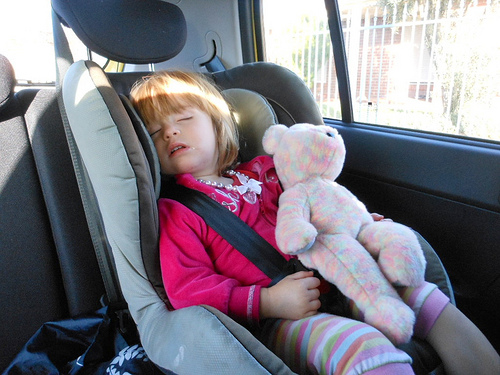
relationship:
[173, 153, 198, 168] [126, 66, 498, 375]
chin of child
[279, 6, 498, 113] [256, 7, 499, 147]
fence through window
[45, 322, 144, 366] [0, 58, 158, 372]
blue article in seat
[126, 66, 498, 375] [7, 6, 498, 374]
child in car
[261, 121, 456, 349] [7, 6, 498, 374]
bear in car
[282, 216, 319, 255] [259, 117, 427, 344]
paw of bear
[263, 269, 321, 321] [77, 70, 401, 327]
hand of kid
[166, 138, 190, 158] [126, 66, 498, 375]
mouth of child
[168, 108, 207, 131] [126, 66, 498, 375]
eye of child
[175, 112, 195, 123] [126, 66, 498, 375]
eye of child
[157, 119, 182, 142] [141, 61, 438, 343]
nose of kid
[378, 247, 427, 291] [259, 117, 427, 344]
paw of bear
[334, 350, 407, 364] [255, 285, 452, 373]
stripe on pants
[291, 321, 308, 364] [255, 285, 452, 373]
stripe on pants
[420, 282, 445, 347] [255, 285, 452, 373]
stripe on pants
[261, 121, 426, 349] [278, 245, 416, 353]
bear in lap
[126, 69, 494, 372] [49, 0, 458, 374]
child in seat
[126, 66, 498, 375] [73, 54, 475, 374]
child in seat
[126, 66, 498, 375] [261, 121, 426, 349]
child holding bear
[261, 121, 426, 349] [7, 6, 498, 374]
bear in car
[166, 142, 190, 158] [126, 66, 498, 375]
mouth of child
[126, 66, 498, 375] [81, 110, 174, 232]
child in carseat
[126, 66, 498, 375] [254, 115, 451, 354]
child holding teddybear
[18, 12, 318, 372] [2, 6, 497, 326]
seat of car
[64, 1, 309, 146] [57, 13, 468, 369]
headrest above carseat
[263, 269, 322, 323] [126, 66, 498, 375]
hand of child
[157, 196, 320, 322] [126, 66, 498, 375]
arm of child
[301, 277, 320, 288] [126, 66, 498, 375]
finger of child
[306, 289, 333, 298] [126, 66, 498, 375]
finger of child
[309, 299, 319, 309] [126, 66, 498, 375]
finger of child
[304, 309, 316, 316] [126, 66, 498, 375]
finger of child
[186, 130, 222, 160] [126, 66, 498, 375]
cheek of child